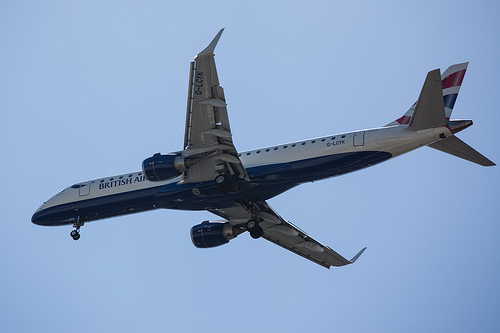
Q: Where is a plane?
A: In the sky.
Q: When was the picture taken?
A: Daytime.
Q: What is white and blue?
A: Airplane.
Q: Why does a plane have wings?
A: To fly.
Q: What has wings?
A: Plane.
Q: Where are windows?
A: On a plane.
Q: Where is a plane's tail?
A: On the back of the plane.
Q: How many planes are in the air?
A: One.